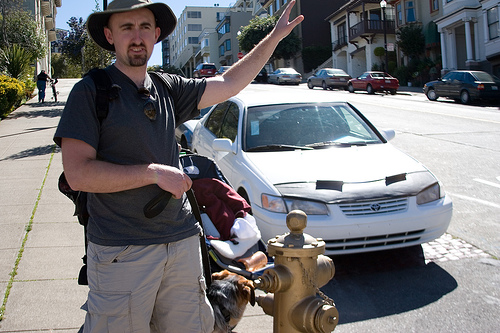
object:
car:
[191, 89, 454, 263]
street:
[170, 69, 500, 332]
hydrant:
[246, 204, 348, 332]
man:
[54, 0, 310, 333]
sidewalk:
[1, 76, 309, 332]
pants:
[78, 235, 217, 332]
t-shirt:
[52, 63, 211, 248]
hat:
[84, 0, 180, 50]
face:
[111, 11, 155, 68]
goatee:
[125, 42, 150, 66]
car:
[421, 69, 500, 104]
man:
[36, 70, 53, 105]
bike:
[49, 79, 60, 103]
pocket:
[79, 291, 134, 332]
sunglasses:
[139, 86, 159, 122]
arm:
[174, 37, 276, 120]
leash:
[142, 189, 178, 219]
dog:
[74, 263, 254, 333]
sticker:
[249, 121, 258, 137]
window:
[241, 100, 387, 154]